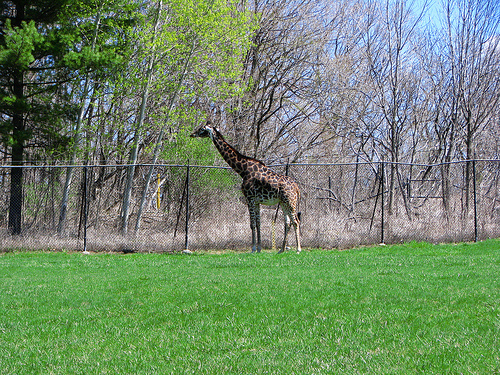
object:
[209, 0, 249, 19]
leaves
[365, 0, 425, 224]
trees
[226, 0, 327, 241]
trees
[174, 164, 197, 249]
poles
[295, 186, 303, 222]
tail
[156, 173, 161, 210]
pipe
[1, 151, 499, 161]
wire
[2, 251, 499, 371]
grass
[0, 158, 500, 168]
pole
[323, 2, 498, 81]
sky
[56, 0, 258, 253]
small sapling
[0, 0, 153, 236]
big tree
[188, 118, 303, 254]
giraffe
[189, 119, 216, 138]
head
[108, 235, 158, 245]
links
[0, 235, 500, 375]
field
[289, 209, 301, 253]
legs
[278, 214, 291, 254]
legs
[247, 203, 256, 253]
legs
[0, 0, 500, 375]
zoo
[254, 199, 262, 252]
legs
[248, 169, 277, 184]
spots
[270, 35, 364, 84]
trees leaves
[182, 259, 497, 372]
ground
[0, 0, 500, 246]
woods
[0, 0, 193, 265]
left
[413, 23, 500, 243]
right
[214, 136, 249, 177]
neck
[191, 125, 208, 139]
face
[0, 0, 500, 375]
photo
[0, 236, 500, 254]
fence line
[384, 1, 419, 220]
tree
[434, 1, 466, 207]
tree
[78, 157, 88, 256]
fencepost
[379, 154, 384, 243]
fencepost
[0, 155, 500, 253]
fence